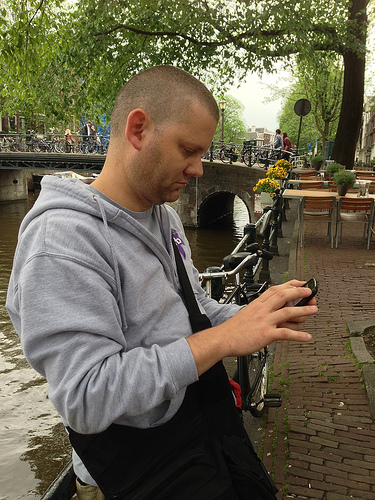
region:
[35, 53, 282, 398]
man looking down at cell phone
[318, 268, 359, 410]
red bricks on walkway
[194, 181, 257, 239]
bridge arch over water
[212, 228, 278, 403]
bike parked against fence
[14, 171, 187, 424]
gray sweatshirt on man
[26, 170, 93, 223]
hood on back of sweatshirt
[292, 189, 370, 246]
backs of chairs at table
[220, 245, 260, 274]
black seat of bike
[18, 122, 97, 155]
bikes on top of bridge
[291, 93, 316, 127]
round sign on pole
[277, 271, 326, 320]
A small black cell phone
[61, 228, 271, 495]
Black cross body bag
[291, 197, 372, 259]
Chairs with wooden backs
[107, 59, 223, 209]
A shaved head of a man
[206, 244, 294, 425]
Bicycle parked next to a fence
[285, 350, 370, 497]
An old brick walk way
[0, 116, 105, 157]
Lots of bikes on a bridge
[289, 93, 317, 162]
A round sign on a pole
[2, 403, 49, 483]
Murky brown looking water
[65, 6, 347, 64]
Large tree branch overhanging the water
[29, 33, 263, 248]
man with buzzed hair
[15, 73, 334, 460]
man using his cellphone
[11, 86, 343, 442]
man wearing a grey hooded sweatshirt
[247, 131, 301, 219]
row of potted flowers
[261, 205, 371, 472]
uneven brick walkway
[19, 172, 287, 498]
black carry bag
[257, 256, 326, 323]
small black cellphone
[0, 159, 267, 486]
dirty brown water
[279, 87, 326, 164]
back of a rounded street sign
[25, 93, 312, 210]
people walking on a bridge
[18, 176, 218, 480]
grey hooded sweat shirt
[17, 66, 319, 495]
man holding cell phone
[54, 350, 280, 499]
black fabric messenger bag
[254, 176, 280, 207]
yellow flowers in pot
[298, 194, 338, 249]
brown wood and metal chair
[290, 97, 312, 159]
metal street sign on pole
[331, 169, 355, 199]
green plant on table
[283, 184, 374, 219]
brown wood dinner table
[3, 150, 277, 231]
stone bridge over water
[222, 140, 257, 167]
bicycle leaning on railing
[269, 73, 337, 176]
a traffic sign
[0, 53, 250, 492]
a body of water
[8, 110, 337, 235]
a bridge over a body of water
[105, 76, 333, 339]
a guy on a cell phone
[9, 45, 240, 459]
a man wearing a grey sweatshirt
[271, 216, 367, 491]
a brick sidewalk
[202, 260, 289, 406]
a bicycle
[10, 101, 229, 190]
people riding bicycles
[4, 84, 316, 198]
people riding bicycles over a bridge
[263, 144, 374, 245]
chairs and tables